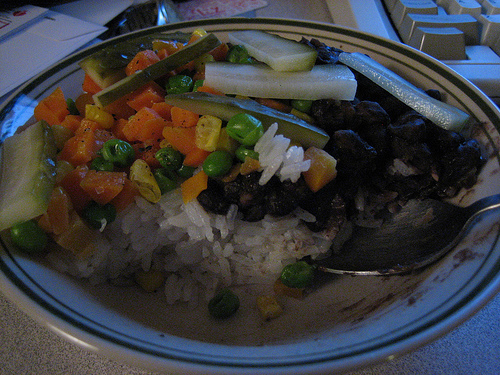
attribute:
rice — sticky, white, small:
[255, 116, 313, 184]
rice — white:
[123, 201, 334, 316]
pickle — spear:
[90, 35, 228, 112]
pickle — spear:
[174, 89, 330, 148]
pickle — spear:
[84, 31, 203, 90]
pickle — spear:
[2, 118, 59, 229]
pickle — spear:
[227, 28, 324, 75]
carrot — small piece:
[123, 109, 168, 140]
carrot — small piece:
[166, 128, 197, 153]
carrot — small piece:
[38, 91, 70, 123]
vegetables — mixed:
[9, 37, 399, 210]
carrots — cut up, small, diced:
[38, 53, 228, 217]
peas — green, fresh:
[203, 112, 259, 178]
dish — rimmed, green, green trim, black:
[4, 17, 494, 365]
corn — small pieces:
[83, 94, 234, 204]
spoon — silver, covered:
[315, 159, 499, 292]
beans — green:
[186, 32, 474, 142]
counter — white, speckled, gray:
[2, 1, 500, 371]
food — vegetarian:
[4, 27, 479, 311]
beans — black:
[199, 91, 482, 239]